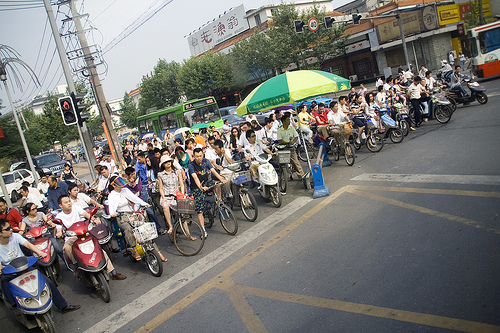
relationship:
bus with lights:
[130, 93, 228, 140] [203, 97, 214, 107]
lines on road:
[129, 182, 499, 331] [11, 78, 499, 333]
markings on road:
[349, 163, 500, 193] [11, 78, 499, 333]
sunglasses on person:
[2, 224, 13, 234] [1, 217, 81, 326]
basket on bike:
[128, 220, 158, 244] [107, 199, 167, 277]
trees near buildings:
[177, 47, 245, 111] [116, 1, 500, 131]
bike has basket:
[107, 199, 167, 277] [128, 220, 158, 244]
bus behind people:
[130, 93, 228, 140] [2, 56, 465, 332]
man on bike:
[47, 194, 130, 292] [44, 206, 115, 304]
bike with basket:
[107, 199, 167, 277] [128, 220, 158, 244]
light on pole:
[57, 93, 78, 127] [64, 1, 128, 172]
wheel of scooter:
[28, 304, 55, 333] [2, 252, 62, 332]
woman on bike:
[106, 172, 172, 265] [107, 199, 167, 277]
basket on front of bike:
[128, 220, 158, 244] [107, 199, 167, 277]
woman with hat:
[106, 172, 172, 265] [109, 174, 129, 189]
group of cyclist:
[4, 60, 456, 319] [157, 147, 254, 254]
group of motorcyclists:
[4, 60, 456, 319] [4, 194, 114, 321]